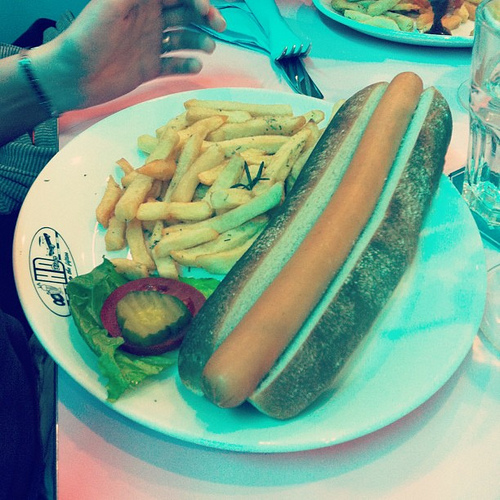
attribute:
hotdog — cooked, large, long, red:
[195, 67, 431, 414]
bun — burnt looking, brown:
[169, 67, 453, 424]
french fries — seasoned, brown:
[90, 96, 344, 280]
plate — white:
[10, 87, 489, 456]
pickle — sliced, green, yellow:
[112, 285, 191, 349]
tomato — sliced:
[88, 274, 211, 356]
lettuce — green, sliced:
[64, 254, 222, 403]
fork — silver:
[239, 0, 315, 66]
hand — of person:
[61, 0, 229, 106]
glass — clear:
[462, 3, 499, 236]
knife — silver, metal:
[274, 54, 326, 101]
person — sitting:
[1, 1, 227, 499]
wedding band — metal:
[160, 33, 172, 56]